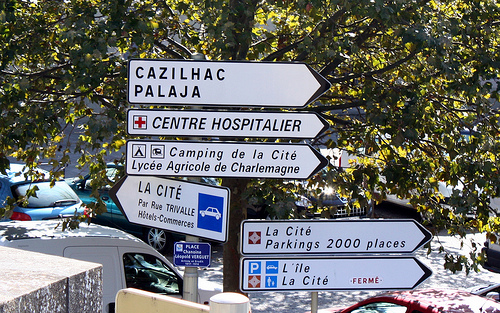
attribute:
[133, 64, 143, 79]
letter — c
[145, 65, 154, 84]
letter — a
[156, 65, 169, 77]
letter — z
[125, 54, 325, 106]
sign — i, h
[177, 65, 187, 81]
letter — l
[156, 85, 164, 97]
letter — l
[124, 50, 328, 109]
sign — j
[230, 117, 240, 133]
letter — s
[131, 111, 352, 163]
sign — white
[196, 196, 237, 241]
picture — blue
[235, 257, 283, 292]
pictures — blue, red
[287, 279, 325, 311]
pole — thin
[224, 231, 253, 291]
trunk — brown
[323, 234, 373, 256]
number — black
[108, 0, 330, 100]
sign — white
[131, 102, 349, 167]
sign — white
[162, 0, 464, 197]
tree — large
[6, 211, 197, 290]
van — white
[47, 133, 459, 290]
lot — full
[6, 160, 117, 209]
car — blue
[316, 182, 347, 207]
hood — shiny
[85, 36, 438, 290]
signs — white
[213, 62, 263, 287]
trunk — brown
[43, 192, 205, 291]
vehicle — white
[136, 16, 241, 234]
signs — white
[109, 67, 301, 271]
signs — white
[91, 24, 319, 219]
signs — white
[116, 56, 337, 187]
signs — white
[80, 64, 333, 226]
signs — white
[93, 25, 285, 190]
signs — white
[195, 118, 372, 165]
signs — white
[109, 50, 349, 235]
signs — white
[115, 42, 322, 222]
signs — white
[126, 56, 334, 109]
sign — street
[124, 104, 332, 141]
sign — street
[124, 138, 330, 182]
sign — street